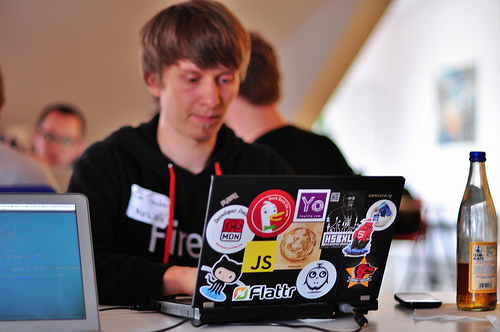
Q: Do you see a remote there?
A: No, there are no remote controls.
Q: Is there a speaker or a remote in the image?
A: No, there are no remote controls or speakers.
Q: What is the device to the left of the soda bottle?
A: The device is a screen.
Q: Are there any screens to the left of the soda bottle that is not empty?
A: Yes, there is a screen to the left of the soda bottle.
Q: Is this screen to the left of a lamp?
A: No, the screen is to the left of the soda bottle.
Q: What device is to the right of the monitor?
A: The device is a screen.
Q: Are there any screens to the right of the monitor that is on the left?
A: Yes, there is a screen to the right of the monitor.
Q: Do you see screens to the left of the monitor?
A: No, the screen is to the right of the monitor.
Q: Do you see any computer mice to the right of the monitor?
A: No, there is a screen to the right of the monitor.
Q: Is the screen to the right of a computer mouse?
A: No, the screen is to the right of a monitor.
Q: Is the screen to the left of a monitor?
A: No, the screen is to the right of a monitor.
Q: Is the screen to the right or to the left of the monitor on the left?
A: The screen is to the right of the monitor.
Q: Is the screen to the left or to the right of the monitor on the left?
A: The screen is to the right of the monitor.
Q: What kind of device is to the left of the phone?
A: The device is a screen.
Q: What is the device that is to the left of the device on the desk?
A: The device is a screen.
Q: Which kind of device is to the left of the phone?
A: The device is a screen.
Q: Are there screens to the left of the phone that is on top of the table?
A: Yes, there is a screen to the left of the phone.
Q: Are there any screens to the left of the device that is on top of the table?
A: Yes, there is a screen to the left of the phone.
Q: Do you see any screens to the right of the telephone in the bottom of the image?
A: No, the screen is to the left of the phone.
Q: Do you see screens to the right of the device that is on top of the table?
A: No, the screen is to the left of the phone.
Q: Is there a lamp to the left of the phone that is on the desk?
A: No, there is a screen to the left of the telephone.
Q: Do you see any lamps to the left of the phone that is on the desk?
A: No, there is a screen to the left of the telephone.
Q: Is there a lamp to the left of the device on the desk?
A: No, there is a screen to the left of the telephone.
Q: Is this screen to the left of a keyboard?
A: No, the screen is to the left of a phone.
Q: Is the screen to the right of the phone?
A: No, the screen is to the left of the phone.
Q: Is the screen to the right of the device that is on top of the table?
A: No, the screen is to the left of the phone.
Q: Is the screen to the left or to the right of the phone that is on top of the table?
A: The screen is to the left of the telephone.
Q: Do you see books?
A: No, there are no books.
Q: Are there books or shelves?
A: No, there are no books or shelves.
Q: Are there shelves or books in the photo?
A: No, there are no books or shelves.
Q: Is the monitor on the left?
A: Yes, the monitor is on the left of the image.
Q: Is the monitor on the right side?
A: No, the monitor is on the left of the image.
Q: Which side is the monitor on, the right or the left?
A: The monitor is on the left of the image.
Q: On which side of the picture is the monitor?
A: The monitor is on the left of the image.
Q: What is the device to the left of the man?
A: The device is a monitor.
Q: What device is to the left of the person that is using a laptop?
A: The device is a monitor.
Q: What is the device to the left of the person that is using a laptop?
A: The device is a monitor.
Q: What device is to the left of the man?
A: The device is a monitor.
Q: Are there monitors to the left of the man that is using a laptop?
A: Yes, there is a monitor to the left of the man.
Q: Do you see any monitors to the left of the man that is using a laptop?
A: Yes, there is a monitor to the left of the man.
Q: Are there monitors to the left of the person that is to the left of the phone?
A: Yes, there is a monitor to the left of the man.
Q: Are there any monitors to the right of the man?
A: No, the monitor is to the left of the man.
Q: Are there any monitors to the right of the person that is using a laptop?
A: No, the monitor is to the left of the man.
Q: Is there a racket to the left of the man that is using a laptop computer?
A: No, there is a monitor to the left of the man.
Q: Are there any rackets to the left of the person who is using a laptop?
A: No, there is a monitor to the left of the man.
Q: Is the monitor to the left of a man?
A: Yes, the monitor is to the left of a man.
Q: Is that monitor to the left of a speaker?
A: No, the monitor is to the left of a man.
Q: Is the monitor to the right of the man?
A: No, the monitor is to the left of the man.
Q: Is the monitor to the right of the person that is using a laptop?
A: No, the monitor is to the left of the man.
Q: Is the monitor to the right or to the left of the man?
A: The monitor is to the left of the man.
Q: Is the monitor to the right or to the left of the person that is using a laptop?
A: The monitor is to the left of the man.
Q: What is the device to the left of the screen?
A: The device is a monitor.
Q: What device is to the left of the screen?
A: The device is a monitor.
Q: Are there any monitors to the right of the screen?
A: No, the monitor is to the left of the screen.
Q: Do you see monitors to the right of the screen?
A: No, the monitor is to the left of the screen.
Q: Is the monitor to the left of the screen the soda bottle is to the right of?
A: Yes, the monitor is to the left of the screen.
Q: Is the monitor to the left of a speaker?
A: No, the monitor is to the left of the screen.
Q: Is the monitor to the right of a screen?
A: No, the monitor is to the left of a screen.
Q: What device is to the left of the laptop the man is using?
A: The device is a monitor.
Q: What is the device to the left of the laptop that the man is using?
A: The device is a monitor.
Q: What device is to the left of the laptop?
A: The device is a monitor.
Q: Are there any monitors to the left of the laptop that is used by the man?
A: Yes, there is a monitor to the left of the laptop.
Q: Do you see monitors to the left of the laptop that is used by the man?
A: Yes, there is a monitor to the left of the laptop.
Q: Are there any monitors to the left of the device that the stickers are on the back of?
A: Yes, there is a monitor to the left of the laptop.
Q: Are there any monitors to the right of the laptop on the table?
A: No, the monitor is to the left of the laptop.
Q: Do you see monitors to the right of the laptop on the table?
A: No, the monitor is to the left of the laptop.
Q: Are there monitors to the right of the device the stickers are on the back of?
A: No, the monitor is to the left of the laptop.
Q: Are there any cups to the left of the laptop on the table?
A: No, there is a monitor to the left of the laptop.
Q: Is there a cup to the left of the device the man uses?
A: No, there is a monitor to the left of the laptop.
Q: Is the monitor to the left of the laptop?
A: Yes, the monitor is to the left of the laptop.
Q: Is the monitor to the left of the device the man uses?
A: Yes, the monitor is to the left of the laptop.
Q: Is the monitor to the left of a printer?
A: No, the monitor is to the left of the laptop.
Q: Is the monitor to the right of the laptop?
A: No, the monitor is to the left of the laptop.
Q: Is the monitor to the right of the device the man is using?
A: No, the monitor is to the left of the laptop.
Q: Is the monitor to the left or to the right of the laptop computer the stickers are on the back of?
A: The monitor is to the left of the laptop computer.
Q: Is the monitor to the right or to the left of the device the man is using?
A: The monitor is to the left of the laptop computer.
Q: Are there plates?
A: No, there are no plates.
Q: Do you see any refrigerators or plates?
A: No, there are no plates or refrigerators.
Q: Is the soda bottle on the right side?
A: Yes, the soda bottle is on the right of the image.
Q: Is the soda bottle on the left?
A: No, the soda bottle is on the right of the image.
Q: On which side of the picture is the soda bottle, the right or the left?
A: The soda bottle is on the right of the image.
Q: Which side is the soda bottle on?
A: The soda bottle is on the right of the image.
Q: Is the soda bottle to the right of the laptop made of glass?
A: Yes, the soda bottle is made of glass.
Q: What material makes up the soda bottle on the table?
A: The soda bottle is made of glass.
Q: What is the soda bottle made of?
A: The soda bottle is made of glass.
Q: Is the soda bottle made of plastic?
A: No, the soda bottle is made of glass.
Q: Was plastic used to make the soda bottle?
A: No, the soda bottle is made of glass.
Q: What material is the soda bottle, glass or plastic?
A: The soda bottle is made of glass.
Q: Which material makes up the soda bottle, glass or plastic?
A: The soda bottle is made of glass.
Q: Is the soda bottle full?
A: Yes, the soda bottle is full.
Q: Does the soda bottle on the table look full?
A: Yes, the soda bottle is full.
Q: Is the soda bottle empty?
A: No, the soda bottle is full.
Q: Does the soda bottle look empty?
A: No, the soda bottle is full.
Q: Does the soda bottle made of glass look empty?
A: No, the soda bottle is full.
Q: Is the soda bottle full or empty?
A: The soda bottle is full.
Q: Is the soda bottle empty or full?
A: The soda bottle is full.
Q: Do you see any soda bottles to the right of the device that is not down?
A: Yes, there is a soda bottle to the right of the telephone.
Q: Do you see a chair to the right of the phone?
A: No, there is a soda bottle to the right of the phone.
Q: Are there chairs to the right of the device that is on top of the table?
A: No, there is a soda bottle to the right of the phone.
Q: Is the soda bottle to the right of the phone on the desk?
A: Yes, the soda bottle is to the right of the telephone.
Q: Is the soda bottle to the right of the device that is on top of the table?
A: Yes, the soda bottle is to the right of the telephone.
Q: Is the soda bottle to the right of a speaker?
A: No, the soda bottle is to the right of the telephone.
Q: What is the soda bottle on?
A: The soda bottle is on the table.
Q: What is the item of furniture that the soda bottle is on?
A: The piece of furniture is a table.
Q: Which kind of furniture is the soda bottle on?
A: The soda bottle is on the table.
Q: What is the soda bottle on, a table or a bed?
A: The soda bottle is on a table.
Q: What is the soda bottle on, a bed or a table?
A: The soda bottle is on a table.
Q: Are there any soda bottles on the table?
A: Yes, there is a soda bottle on the table.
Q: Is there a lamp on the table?
A: No, there is a soda bottle on the table.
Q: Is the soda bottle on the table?
A: Yes, the soda bottle is on the table.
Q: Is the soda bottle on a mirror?
A: No, the soda bottle is on the table.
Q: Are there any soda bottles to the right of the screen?
A: Yes, there is a soda bottle to the right of the screen.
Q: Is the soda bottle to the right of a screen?
A: Yes, the soda bottle is to the right of a screen.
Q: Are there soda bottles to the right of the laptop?
A: Yes, there is a soda bottle to the right of the laptop.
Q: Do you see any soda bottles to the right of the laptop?
A: Yes, there is a soda bottle to the right of the laptop.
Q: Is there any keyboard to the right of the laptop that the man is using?
A: No, there is a soda bottle to the right of the laptop.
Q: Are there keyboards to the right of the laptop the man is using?
A: No, there is a soda bottle to the right of the laptop.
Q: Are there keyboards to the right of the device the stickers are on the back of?
A: No, there is a soda bottle to the right of the laptop.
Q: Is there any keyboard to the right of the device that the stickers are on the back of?
A: No, there is a soda bottle to the right of the laptop.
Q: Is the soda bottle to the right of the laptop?
A: Yes, the soda bottle is to the right of the laptop.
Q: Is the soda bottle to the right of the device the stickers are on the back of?
A: Yes, the soda bottle is to the right of the laptop.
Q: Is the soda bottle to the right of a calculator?
A: No, the soda bottle is to the right of the laptop.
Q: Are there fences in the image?
A: No, there are no fences.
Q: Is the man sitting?
A: Yes, the man is sitting.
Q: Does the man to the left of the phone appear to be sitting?
A: Yes, the man is sitting.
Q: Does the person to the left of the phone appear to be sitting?
A: Yes, the man is sitting.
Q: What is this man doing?
A: The man is sitting.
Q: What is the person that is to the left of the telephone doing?
A: The man is sitting.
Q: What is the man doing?
A: The man is sitting.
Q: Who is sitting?
A: The man is sitting.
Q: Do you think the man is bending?
A: No, the man is sitting.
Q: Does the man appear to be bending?
A: No, the man is sitting.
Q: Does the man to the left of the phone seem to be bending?
A: No, the man is sitting.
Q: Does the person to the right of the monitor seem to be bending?
A: No, the man is sitting.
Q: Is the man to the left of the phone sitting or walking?
A: The man is sitting.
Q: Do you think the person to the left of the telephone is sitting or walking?
A: The man is sitting.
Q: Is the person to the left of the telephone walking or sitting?
A: The man is sitting.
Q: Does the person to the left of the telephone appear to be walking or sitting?
A: The man is sitting.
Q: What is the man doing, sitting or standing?
A: The man is sitting.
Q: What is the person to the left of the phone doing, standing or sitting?
A: The man is sitting.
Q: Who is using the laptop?
A: The man is using the laptop.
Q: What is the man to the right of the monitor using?
A: The man is using a laptop.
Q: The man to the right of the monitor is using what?
A: The man is using a laptop.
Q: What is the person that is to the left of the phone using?
A: The man is using a laptop.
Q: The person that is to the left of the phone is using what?
A: The man is using a laptop.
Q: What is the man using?
A: The man is using a laptop.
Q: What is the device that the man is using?
A: The device is a laptop.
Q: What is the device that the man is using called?
A: The device is a laptop.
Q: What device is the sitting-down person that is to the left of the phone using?
A: The man is using a laptop.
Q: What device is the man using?
A: The man is using a laptop.